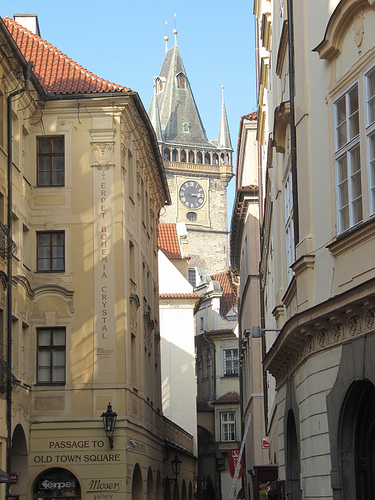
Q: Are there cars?
A: No, there are no cars.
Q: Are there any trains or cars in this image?
A: No, there are no cars or trains.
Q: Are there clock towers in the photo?
A: Yes, there is a clock tower.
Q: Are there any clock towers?
A: Yes, there is a clock tower.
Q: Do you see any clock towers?
A: Yes, there is a clock tower.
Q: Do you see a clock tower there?
A: Yes, there is a clock tower.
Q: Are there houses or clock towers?
A: Yes, there is a clock tower.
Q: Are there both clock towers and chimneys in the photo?
A: No, there is a clock tower but no chimneys.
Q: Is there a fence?
A: No, there are no fences.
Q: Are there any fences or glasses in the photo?
A: No, there are no fences or glasses.